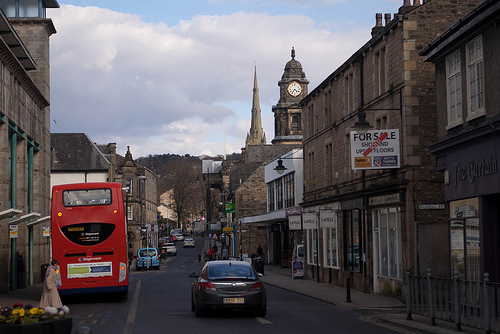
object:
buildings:
[0, 0, 500, 334]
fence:
[403, 267, 499, 334]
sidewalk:
[253, 265, 498, 334]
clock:
[287, 80, 304, 97]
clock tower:
[270, 46, 310, 145]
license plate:
[222, 297, 245, 304]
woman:
[38, 259, 62, 310]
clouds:
[45, 3, 374, 155]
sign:
[349, 128, 401, 171]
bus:
[50, 181, 135, 301]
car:
[133, 247, 160, 270]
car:
[161, 243, 177, 256]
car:
[159, 239, 170, 246]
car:
[175, 233, 185, 241]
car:
[181, 238, 195, 248]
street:
[0, 234, 414, 334]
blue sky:
[45, 0, 406, 157]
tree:
[156, 157, 207, 230]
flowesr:
[0, 302, 69, 317]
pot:
[10, 316, 73, 333]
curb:
[127, 265, 135, 271]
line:
[126, 279, 141, 324]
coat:
[40, 265, 64, 309]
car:
[188, 260, 268, 318]